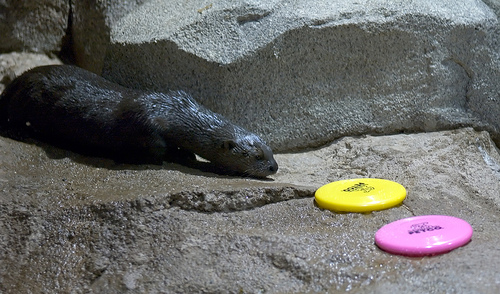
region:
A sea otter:
[4, 55, 289, 187]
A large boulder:
[78, 0, 497, 136]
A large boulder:
[13, 97, 492, 289]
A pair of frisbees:
[301, 161, 478, 271]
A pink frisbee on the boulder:
[367, 201, 482, 264]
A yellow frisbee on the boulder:
[310, 160, 406, 212]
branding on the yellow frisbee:
[331, 170, 398, 197]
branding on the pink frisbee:
[403, 214, 450, 238]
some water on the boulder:
[7, 130, 399, 292]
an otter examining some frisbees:
[9, 49, 279, 185]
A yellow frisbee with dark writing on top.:
[311, 175, 406, 213]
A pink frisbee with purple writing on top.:
[371, 212, 475, 257]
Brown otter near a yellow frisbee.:
[3, 62, 279, 177]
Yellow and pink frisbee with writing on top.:
[313, 176, 474, 253]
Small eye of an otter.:
[251, 153, 264, 160]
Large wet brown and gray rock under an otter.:
[2, 145, 187, 290]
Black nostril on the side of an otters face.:
[267, 165, 275, 172]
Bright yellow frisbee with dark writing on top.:
[314, 178, 408, 210]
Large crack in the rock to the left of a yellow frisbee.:
[172, 182, 313, 214]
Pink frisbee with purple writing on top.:
[367, 212, 474, 257]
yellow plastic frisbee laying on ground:
[300, 164, 415, 207]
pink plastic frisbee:
[362, 212, 476, 262]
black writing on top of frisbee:
[343, 179, 376, 196]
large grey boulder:
[231, 7, 441, 117]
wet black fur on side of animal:
[60, 89, 125, 126]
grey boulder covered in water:
[57, 166, 153, 200]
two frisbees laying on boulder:
[283, 140, 496, 287]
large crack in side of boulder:
[438, 40, 483, 117]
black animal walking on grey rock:
[0, 54, 295, 188]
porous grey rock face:
[282, 33, 378, 128]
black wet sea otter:
[12, 62, 317, 167]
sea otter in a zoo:
[16, 41, 284, 189]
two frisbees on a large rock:
[291, 159, 496, 261]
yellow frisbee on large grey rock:
[308, 152, 413, 229]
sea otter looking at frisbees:
[192, 106, 443, 257]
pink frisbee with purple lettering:
[365, 205, 479, 275]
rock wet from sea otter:
[19, 166, 149, 273]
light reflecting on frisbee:
[356, 195, 393, 212]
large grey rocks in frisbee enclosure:
[36, 3, 478, 276]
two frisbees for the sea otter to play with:
[293, 139, 472, 265]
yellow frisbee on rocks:
[320, 148, 372, 197]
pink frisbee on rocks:
[366, 195, 492, 277]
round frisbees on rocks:
[303, 153, 465, 275]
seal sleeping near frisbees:
[2, 63, 259, 200]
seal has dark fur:
[30, 44, 183, 131]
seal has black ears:
[189, 138, 254, 171]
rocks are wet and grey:
[95, 241, 223, 290]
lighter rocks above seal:
[138, 3, 261, 60]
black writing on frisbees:
[334, 158, 469, 260]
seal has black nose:
[266, 150, 287, 185]